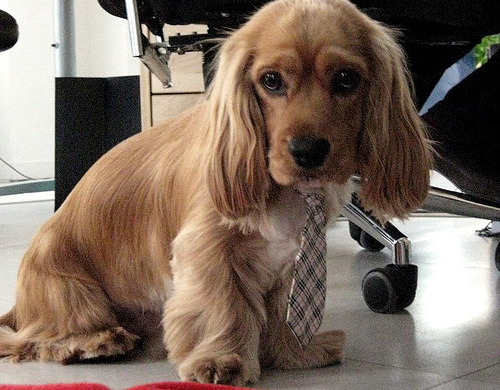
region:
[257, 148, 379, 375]
the dog is wearing a tie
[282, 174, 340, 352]
the dog is wearing a tie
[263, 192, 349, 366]
the dog is wearing a tie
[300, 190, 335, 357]
the dog is wearing a tie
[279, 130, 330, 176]
dog's nose is black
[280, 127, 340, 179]
dog's nose is black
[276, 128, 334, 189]
dog's nose is black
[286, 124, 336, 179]
dog's nose is black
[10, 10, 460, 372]
This is a puppy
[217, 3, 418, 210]
The puppy is looking at the camera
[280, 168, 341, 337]
The puppy is wearing a tie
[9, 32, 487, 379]
The puppy is on the floor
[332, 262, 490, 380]
The floor is made of tile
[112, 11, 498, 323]
A desk chair behind the dog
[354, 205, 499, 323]
The chair is on wheels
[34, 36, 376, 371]
Only the right side of the dog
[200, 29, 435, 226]
The dog has long furry ears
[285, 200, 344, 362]
The necktie is black and red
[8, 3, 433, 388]
A dog.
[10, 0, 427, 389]
A tan dog.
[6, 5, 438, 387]
A brown colored dog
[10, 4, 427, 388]
The dog is wearing a tie.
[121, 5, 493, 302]
A chair on wheels behind the dog.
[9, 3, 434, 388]
The dog is on the floor.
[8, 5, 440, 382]
A tie is around the dog's neck.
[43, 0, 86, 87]
A metal pole behind the dog.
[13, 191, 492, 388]
The floor is grey tile.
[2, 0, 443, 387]
tan dog on floor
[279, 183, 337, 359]
plaid tie on tan dog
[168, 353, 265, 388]
dog paw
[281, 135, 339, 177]
one dog nose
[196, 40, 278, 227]
long tan dog ear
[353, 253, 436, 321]
black wheel on floor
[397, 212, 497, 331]
sunlight reflected on tiled floor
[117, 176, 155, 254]
long tan dog hair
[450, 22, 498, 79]
trees sees through gap in chair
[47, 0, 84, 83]
metal pole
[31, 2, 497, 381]
this is a dog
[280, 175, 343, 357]
this is a tie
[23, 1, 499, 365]
a dog wearing a tie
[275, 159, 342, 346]
the tie is plaid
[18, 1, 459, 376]
the dog is sitting down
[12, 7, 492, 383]
the dog is light brown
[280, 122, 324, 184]
black nose on dog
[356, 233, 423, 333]
a black rolling foot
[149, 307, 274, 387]
front paw of dog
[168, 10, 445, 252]
long hair on dogs ears